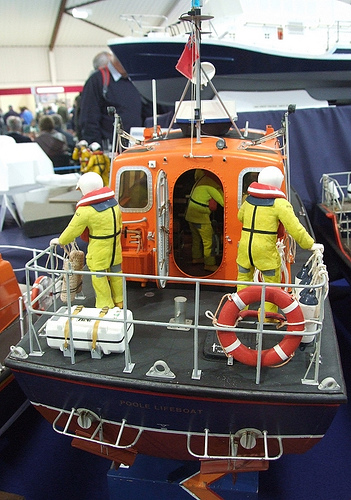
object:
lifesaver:
[218, 285, 305, 366]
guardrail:
[23, 261, 337, 387]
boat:
[3, 0, 347, 462]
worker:
[235, 167, 325, 323]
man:
[49, 171, 123, 310]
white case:
[45, 305, 134, 354]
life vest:
[247, 181, 287, 200]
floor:
[32, 445, 189, 498]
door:
[172, 168, 225, 278]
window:
[118, 169, 149, 210]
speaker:
[191, 61, 216, 85]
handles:
[147, 231, 155, 241]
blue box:
[174, 100, 238, 136]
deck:
[47, 265, 330, 390]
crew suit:
[58, 202, 123, 309]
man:
[185, 169, 218, 272]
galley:
[173, 176, 216, 277]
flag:
[175, 35, 199, 81]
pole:
[194, 36, 202, 142]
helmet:
[76, 172, 104, 197]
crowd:
[6, 98, 90, 163]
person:
[17, 103, 32, 130]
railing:
[298, 242, 330, 388]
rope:
[311, 248, 328, 285]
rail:
[23, 249, 78, 362]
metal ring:
[309, 267, 334, 297]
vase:
[149, 76, 161, 140]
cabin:
[108, 124, 293, 294]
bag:
[298, 287, 319, 351]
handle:
[311, 269, 330, 286]